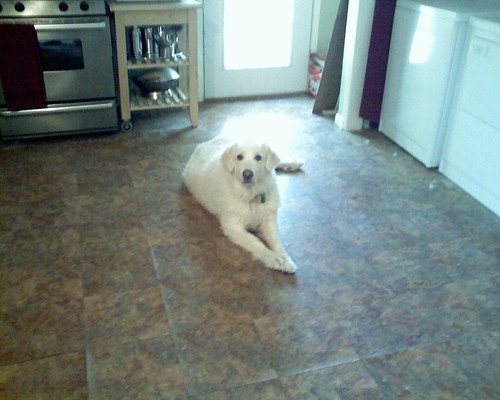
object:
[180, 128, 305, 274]
dog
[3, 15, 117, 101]
oven door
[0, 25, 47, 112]
maroon towel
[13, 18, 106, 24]
door handle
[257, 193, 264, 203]
collar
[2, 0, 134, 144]
stove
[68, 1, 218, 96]
table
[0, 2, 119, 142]
oven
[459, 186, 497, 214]
tile edges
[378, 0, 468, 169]
dryer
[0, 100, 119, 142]
drawer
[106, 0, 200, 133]
cart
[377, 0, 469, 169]
washer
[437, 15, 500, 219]
dryer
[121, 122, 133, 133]
wheel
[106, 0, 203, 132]
butcher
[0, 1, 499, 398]
floor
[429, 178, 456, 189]
paper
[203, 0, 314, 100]
door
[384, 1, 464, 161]
white washer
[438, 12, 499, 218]
white dryer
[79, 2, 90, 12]
knob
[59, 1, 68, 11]
knob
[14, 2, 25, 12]
knob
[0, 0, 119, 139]
appliance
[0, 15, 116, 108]
door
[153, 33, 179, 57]
kitchenware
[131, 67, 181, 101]
kitchenware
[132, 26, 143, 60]
kitchenware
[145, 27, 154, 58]
kitchenware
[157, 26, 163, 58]
kitchenware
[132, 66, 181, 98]
wok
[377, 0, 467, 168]
appliance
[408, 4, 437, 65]
reflection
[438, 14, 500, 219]
appliances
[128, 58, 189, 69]
shelves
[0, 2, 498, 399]
kitchen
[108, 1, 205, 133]
kitchen table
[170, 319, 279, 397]
tile